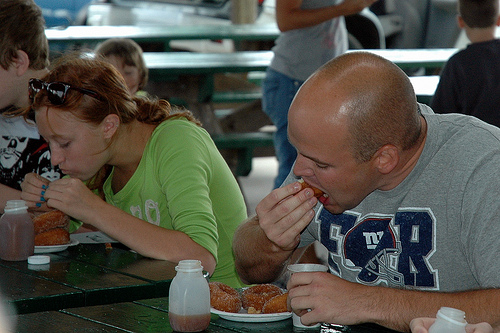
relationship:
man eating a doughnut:
[245, 48, 497, 332] [298, 180, 327, 201]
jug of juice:
[168, 254, 217, 331] [170, 313, 205, 331]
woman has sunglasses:
[28, 47, 240, 267] [32, 80, 89, 105]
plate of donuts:
[226, 310, 271, 323] [209, 279, 289, 313]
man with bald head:
[245, 48, 497, 332] [300, 70, 373, 126]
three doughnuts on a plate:
[209, 279, 289, 313] [226, 310, 271, 323]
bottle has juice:
[0, 199, 34, 261] [170, 313, 205, 331]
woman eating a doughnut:
[28, 47, 240, 267] [298, 180, 327, 201]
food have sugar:
[28, 213, 295, 332] [40, 215, 56, 227]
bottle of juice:
[9, 223, 29, 260] [170, 313, 205, 331]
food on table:
[28, 213, 295, 332] [88, 259, 122, 283]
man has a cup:
[245, 48, 497, 332] [287, 262, 330, 278]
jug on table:
[168, 254, 217, 331] [88, 259, 122, 283]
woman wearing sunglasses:
[28, 47, 240, 267] [32, 80, 89, 105]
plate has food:
[226, 310, 271, 323] [28, 213, 295, 332]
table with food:
[88, 259, 122, 283] [28, 213, 295, 332]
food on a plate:
[28, 213, 295, 332] [226, 310, 271, 323]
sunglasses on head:
[32, 80, 89, 105] [24, 70, 130, 121]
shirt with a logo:
[163, 141, 210, 211] [315, 209, 442, 290]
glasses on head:
[32, 80, 89, 105] [282, 57, 427, 186]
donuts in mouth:
[208, 282, 287, 314] [298, 180, 327, 201]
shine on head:
[324, 78, 367, 118] [282, 57, 427, 186]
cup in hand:
[287, 262, 330, 278] [270, 195, 312, 246]